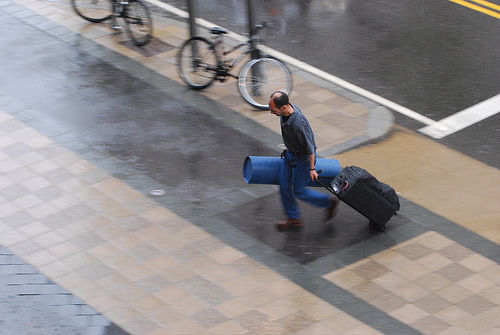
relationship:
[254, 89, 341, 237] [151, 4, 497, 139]
man near road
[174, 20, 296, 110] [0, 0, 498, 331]
bicycle on sidewalk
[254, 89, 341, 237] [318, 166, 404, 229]
man has suitcase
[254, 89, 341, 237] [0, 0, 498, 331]
man on sidewalk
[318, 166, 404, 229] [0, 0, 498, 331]
suitcase on sidewalk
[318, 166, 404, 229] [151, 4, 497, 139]
suitcase near road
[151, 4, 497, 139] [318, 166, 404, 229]
road near suitcase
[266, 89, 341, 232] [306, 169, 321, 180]
man wearing watch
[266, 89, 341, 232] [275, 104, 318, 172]
man wearing shirt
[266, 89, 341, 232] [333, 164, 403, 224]
man pulling suitcase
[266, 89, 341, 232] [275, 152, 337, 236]
man wearing jeans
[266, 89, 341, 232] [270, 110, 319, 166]
man wearing shirt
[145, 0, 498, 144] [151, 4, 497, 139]
lines painted on road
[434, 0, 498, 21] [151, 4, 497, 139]
lines painted on road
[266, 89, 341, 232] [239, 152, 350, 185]
man carrying container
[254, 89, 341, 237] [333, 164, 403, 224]
man rolling suitcase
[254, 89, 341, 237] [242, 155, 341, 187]
man carrying container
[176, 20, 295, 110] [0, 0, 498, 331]
bicycle parked on sidewalk